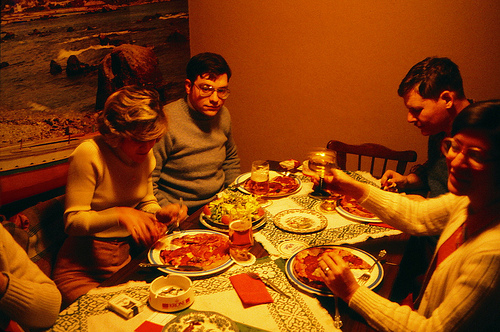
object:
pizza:
[162, 233, 232, 271]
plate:
[147, 229, 240, 277]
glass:
[227, 206, 254, 251]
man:
[150, 50, 243, 208]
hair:
[187, 51, 233, 81]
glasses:
[190, 80, 231, 99]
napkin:
[228, 270, 273, 306]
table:
[27, 159, 431, 332]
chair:
[325, 140, 419, 179]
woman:
[317, 101, 500, 332]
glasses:
[439, 134, 490, 163]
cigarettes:
[107, 292, 140, 318]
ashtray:
[149, 275, 195, 310]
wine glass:
[310, 147, 338, 199]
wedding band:
[325, 267, 330, 271]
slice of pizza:
[302, 252, 343, 279]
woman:
[51, 86, 178, 305]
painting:
[0, 2, 190, 172]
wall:
[1, 2, 195, 214]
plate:
[272, 208, 328, 233]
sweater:
[155, 98, 240, 203]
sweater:
[63, 137, 162, 241]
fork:
[357, 245, 388, 286]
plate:
[284, 243, 385, 297]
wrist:
[343, 280, 368, 308]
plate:
[234, 168, 304, 197]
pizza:
[245, 175, 299, 196]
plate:
[336, 194, 380, 221]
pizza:
[340, 195, 375, 222]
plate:
[200, 193, 268, 233]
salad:
[202, 190, 265, 224]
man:
[382, 55, 478, 203]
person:
[0, 220, 63, 326]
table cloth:
[55, 259, 335, 331]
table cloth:
[217, 158, 415, 260]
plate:
[162, 313, 229, 332]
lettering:
[160, 297, 192, 308]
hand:
[316, 249, 359, 298]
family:
[2, 46, 499, 330]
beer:
[230, 220, 251, 230]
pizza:
[296, 247, 371, 291]